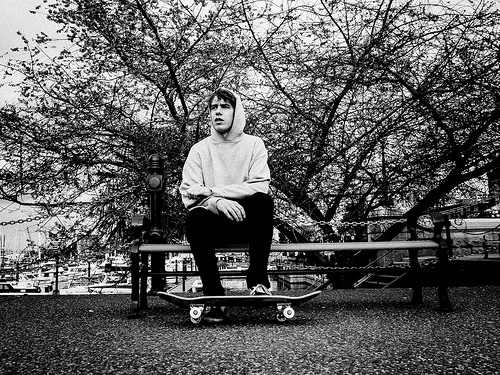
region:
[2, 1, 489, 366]
picture is black and white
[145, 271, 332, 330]
man stepping on skateboard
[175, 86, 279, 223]
man wears a hoodie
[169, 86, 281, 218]
hoodie is gray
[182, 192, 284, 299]
man wears black pants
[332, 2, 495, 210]
no leaves on trees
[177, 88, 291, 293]
man looking to his right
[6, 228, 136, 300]
boat in the background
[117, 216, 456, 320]
man sitting on bench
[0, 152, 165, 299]
chain is tied to a post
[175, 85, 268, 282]
this is the man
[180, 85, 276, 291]
the man is sitted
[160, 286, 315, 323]
this is the skate board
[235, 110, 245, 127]
the jacket has hood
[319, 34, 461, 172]
the tree is branchy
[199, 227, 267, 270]
the trousers are black in color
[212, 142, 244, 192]
the hood is white in color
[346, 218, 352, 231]
the chain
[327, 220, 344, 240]
the chain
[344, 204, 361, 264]
the chain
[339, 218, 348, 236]
the chain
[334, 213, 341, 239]
the chain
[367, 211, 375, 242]
the chain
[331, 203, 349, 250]
the chain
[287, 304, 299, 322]
the wheels are visible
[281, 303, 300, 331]
the wheels are visible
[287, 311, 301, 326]
the wheels are visible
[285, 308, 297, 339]
the wheels are visible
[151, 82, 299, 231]
Young man wearing a white hoodie with the hood up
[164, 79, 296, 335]
Young man sitting on a bench with his feet resting on a skateboard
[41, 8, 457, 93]
Leafless branches of a tree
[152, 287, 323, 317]
Black skateboard with light rim sitting on the ground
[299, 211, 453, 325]
Bench with metal chains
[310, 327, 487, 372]
Ground covered in leaves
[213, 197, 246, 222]
Young man's hand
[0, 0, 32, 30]
Cloud free sky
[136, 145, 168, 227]
Black metal pole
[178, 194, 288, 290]
Black pants